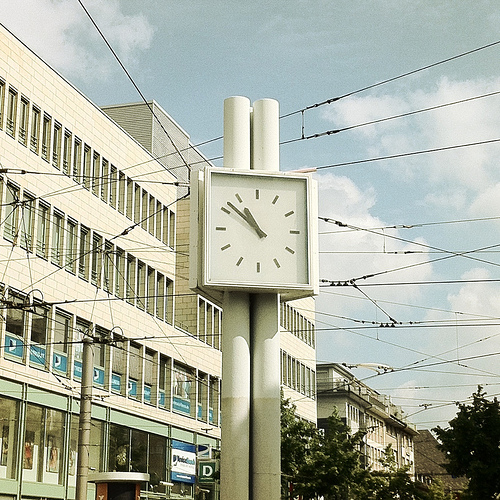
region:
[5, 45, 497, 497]
City block with many overhead power lines and a clock tower.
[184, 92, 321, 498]
Modern white street clock tower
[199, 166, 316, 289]
White analog clock face displaying time of 10:52.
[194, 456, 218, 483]
White capital letter D on sign.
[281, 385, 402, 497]
Green trees in city street environment.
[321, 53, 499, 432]
Numerous overhead power lines over street against cloudy sky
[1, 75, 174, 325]
Two floors of many crowded building windows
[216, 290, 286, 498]
Round, white, pipe-like clock tower pole supports.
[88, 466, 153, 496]
Building street level entry door overhanging awning.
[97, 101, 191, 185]
Cube-like construction on top of building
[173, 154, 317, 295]
A clock on the pole.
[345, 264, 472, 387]
Wires in the sky.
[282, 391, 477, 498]
Trees in front of the building.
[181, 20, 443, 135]
The sky is clear and blue.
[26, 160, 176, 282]
Windows on the building.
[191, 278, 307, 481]
The pole has a clock on it.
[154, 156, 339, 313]
The clock is white.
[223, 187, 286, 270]
The numbers on the clock is black.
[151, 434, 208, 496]
A blue and white sign on the window.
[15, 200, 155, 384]
Wires in front of the building.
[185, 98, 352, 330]
white clock on two white poles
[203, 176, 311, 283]
clock has black markings for hours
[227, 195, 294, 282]
two black hands on clock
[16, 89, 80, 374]
grey blinds in windows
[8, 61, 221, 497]
building is off white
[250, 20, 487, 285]
sky is blue with few clouds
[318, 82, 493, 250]
clouds in sky are thin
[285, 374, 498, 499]
few trees to right of building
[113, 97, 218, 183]
tall and grey roof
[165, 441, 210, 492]
blue and white sign on building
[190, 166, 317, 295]
white clock with black number markings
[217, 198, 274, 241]
black small and big hand of clock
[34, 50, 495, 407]
power lines running behind block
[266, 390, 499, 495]
two trees behind clock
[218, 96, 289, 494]
white poles clocks are attached to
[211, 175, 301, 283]
black markings on white clock face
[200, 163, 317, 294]
white frame of clock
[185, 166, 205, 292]
edge of clock on other side of poles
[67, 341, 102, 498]
utility pole with black power lines attached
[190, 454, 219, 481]
white letter D on green sign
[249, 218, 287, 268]
part of a clock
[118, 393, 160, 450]
part of a window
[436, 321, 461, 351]
part of a cloud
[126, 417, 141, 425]
part of a window